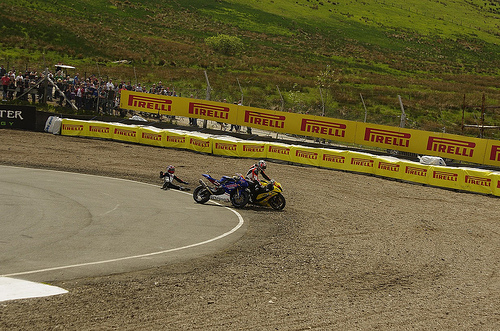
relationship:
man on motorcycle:
[244, 159, 272, 201] [232, 177, 287, 213]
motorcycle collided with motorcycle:
[232, 177, 287, 213] [192, 172, 234, 203]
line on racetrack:
[1, 162, 243, 279] [1, 129, 499, 329]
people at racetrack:
[2, 66, 176, 120] [1, 129, 499, 329]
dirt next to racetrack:
[0, 129, 499, 327] [0, 160, 249, 286]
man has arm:
[157, 164, 193, 193] [175, 173, 190, 184]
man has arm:
[157, 164, 193, 193] [157, 169, 166, 179]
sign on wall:
[63, 94, 500, 189] [0, 102, 499, 200]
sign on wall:
[320, 145, 346, 172] [0, 102, 499, 200]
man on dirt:
[157, 164, 193, 193] [0, 129, 499, 327]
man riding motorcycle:
[244, 159, 272, 201] [232, 177, 287, 213]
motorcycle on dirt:
[232, 177, 287, 213] [0, 129, 499, 327]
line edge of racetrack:
[1, 162, 243, 279] [0, 160, 249, 286]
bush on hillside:
[205, 28, 246, 55] [1, 2, 500, 71]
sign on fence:
[63, 94, 500, 189] [3, 56, 500, 165]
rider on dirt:
[157, 164, 193, 193] [0, 129, 499, 327]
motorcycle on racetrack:
[192, 172, 234, 203] [1, 129, 499, 329]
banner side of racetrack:
[119, 85, 499, 163] [1, 129, 499, 329]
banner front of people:
[0, 102, 38, 130] [2, 66, 176, 120]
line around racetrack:
[1, 162, 243, 279] [0, 160, 249, 286]